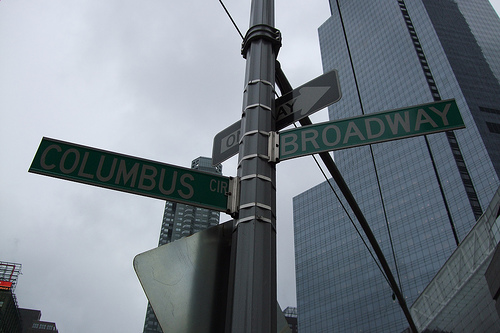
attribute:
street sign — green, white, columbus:
[28, 136, 231, 215]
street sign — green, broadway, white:
[277, 98, 464, 161]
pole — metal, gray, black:
[226, 1, 284, 332]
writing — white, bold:
[40, 144, 228, 201]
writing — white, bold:
[281, 102, 452, 157]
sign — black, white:
[212, 70, 342, 168]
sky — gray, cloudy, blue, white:
[1, 1, 333, 332]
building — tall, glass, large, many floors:
[293, 1, 499, 333]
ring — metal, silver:
[244, 79, 275, 98]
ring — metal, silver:
[242, 103, 272, 119]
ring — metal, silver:
[238, 130, 270, 145]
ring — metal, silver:
[238, 153, 270, 170]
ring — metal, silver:
[241, 172, 275, 188]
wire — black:
[219, 1, 396, 293]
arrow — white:
[295, 86, 331, 115]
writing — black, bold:
[226, 98, 297, 148]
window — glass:
[308, 214, 314, 221]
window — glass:
[393, 171, 400, 181]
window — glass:
[409, 150, 417, 159]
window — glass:
[418, 202, 426, 211]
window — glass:
[357, 175, 365, 182]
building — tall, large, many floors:
[142, 156, 225, 332]